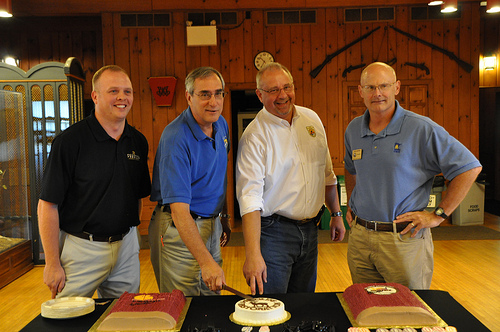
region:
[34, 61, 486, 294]
4 men in collared shirts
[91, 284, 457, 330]
three cake on the table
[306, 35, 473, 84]
wall decor resembles guns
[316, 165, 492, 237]
several trash and recycle bins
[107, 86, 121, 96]
the eye of a person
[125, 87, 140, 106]
the eye of a person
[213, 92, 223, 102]
the eye of a person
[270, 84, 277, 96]
the eye of a person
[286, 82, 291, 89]
the eye of a person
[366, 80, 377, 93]
the eye of a person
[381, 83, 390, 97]
the eye of a person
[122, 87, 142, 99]
the eye of a person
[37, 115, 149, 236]
A black shirt on a man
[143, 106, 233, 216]
A blue shirt on a man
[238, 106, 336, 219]
A white shirt on a man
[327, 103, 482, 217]
A blue shirt on a man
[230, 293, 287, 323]
A cake on a table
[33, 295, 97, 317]
A pile of plates on a table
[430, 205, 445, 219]
A black watch on a wrist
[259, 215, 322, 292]
Blue jeans on a man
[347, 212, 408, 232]
A brown belt on a man's waist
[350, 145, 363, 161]
A tag on a man's shirt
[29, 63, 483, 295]
Four men posing.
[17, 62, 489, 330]
Four men standing in front of cakes.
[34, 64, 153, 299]
A blond man in a black shirt.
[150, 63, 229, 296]
A grey haired man in a blue shirt.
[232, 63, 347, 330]
A man wearing glasses pointing to a round cake.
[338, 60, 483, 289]
A man wearing a watch.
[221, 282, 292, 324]
A round cake with a knife in it.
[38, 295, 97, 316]
A stack of paper plates.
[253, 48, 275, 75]
A round wall clock.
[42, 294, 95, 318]
stack of white plated on the table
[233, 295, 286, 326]
small, circular cake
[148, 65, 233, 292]
man holding knife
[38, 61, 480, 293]
men posing for a picture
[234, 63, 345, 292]
guy wearing a white shirt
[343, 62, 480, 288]
man wearing a light blue shirt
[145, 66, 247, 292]
man wearing a bright blue shirt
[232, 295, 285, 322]
circular white cake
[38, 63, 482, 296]
men posing together for a picture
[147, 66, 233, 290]
man holding a knife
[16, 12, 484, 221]
a wooden wall behind the men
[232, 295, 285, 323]
a small white cake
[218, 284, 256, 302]
a silver knife utensil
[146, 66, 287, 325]
a man cutting a cake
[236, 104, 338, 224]
a man's white shirt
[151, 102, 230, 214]
a man's blue polo shirt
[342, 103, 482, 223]
a man's blue polo shirt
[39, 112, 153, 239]
a man's black polo shirt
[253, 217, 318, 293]
a pair of blue jeans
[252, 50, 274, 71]
a wall clock in distance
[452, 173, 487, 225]
a lined trash can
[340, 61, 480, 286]
Bald man wearing a blue shirt and khakis.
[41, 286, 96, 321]
Stack of paper plates on the table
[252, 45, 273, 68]
Clock on the wall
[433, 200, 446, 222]
Watch on man's left wrist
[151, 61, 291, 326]
Man in a blue shirt cutting a cake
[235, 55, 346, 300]
Man wearing a white shirt and blue jeans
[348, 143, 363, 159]
Name tag on man's shirt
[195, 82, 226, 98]
Glasses on man's face